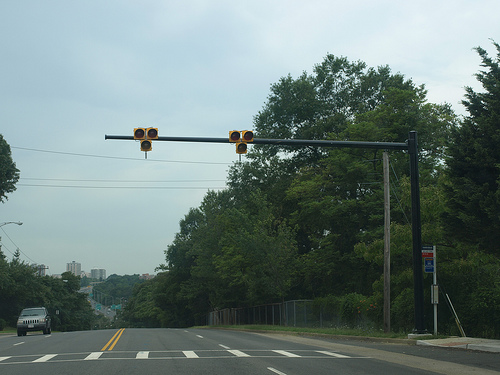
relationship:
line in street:
[102, 327, 126, 352] [8, 323, 498, 374]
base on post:
[416, 329, 451, 344] [412, 224, 458, 341]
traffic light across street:
[229, 130, 254, 154] [8, 323, 498, 374]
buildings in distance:
[42, 253, 107, 290] [9, 247, 138, 326]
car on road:
[9, 302, 56, 337] [20, 337, 87, 362]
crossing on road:
[0, 345, 364, 374] [2, 328, 455, 374]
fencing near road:
[206, 300, 309, 327] [1, 328, 495, 373]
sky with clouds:
[0, 2, 497, 277] [66, 156, 140, 206]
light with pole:
[134, 125, 160, 156] [102, 125, 432, 337]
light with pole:
[224, 128, 255, 156] [102, 125, 432, 337]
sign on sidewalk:
[419, 242, 444, 337] [416, 332, 484, 358]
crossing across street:
[0, 349, 371, 362] [8, 323, 498, 374]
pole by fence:
[375, 138, 407, 338] [210, 290, 420, 324]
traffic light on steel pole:
[228, 125, 255, 157] [397, 122, 438, 300]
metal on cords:
[443, 297, 468, 338] [432, 283, 482, 348]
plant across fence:
[338, 289, 373, 327] [203, 291, 380, 328]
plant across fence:
[301, 292, 381, 329] [203, 291, 380, 328]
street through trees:
[73, 281, 123, 324] [48, 270, 151, 322]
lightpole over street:
[109, 132, 409, 322] [16, 329, 346, 371]